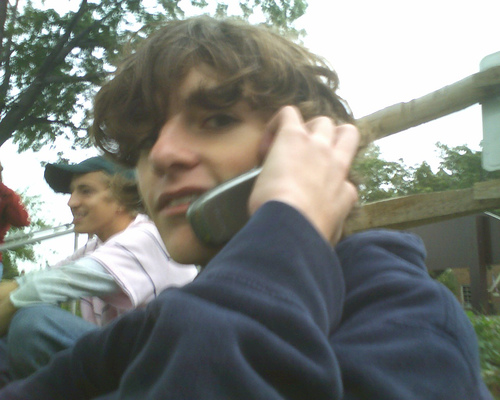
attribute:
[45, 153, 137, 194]
cap — green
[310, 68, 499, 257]
wood fence — wooden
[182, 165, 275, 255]
mobile phone — black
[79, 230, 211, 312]
shirt — pink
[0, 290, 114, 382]
jeans — blue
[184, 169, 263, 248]
phone — silver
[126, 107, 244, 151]
eyes — brown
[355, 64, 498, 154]
post — wooden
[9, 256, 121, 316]
sleeve — white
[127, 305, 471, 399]
jumper — black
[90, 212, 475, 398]
sweatshirt — blue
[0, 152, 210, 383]
shirt — pink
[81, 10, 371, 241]
hair — curly, brown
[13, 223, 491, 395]
jumper — blue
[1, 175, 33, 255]
clothing — red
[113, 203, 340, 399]
sleeve — blue